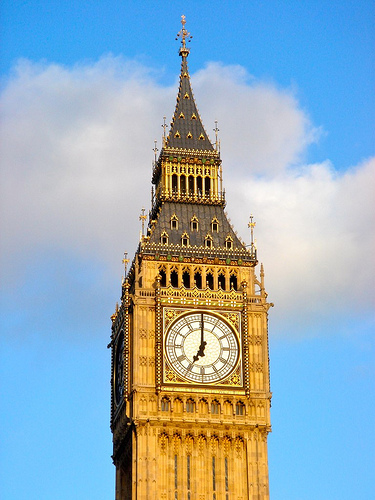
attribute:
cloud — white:
[0, 53, 373, 339]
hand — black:
[199, 311, 205, 357]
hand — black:
[193, 340, 207, 363]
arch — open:
[234, 399, 247, 416]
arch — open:
[223, 398, 235, 417]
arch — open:
[210, 393, 221, 413]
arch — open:
[186, 394, 196, 412]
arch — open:
[158, 392, 172, 411]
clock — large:
[163, 311, 240, 386]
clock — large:
[163, 305, 245, 383]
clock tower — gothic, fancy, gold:
[74, 32, 292, 498]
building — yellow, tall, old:
[79, 13, 296, 499]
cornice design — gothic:
[131, 256, 261, 293]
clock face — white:
[164, 311, 237, 390]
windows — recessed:
[156, 210, 239, 249]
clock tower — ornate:
[73, 13, 300, 482]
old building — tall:
[47, 11, 295, 496]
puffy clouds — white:
[14, 63, 369, 319]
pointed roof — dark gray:
[150, 19, 232, 152]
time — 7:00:
[191, 313, 214, 365]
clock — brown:
[156, 306, 241, 388]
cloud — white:
[7, 57, 365, 319]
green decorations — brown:
[256, 261, 273, 299]